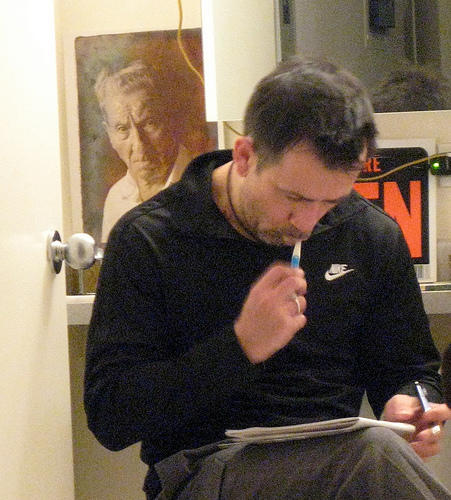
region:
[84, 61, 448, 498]
A guy sitting down writing.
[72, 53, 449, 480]
A man looking down while brushing his teeth.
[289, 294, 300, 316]
A ring.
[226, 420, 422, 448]
A white paper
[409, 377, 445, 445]
A writing utensil.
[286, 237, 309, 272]
A blue and white handled toothbrush.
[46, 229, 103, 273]
A silver doorknob.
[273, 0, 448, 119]
A mirror.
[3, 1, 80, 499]
A white door.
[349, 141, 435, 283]
A orange and black sign.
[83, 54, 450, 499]
man brushing his teeth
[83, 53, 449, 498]
man wearing black Nike brand shirt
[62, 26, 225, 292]
poster of a man on the back wall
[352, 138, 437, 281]
part of an "YES WE'RE OPEN" sign on the back wall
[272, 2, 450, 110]
mirror showing part of the back of the man's head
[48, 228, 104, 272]
silver colored doorknob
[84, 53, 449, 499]
man wearing a ring on the finger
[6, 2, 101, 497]
pink colored open door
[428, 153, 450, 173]
black box with an illuminated green light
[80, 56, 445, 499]
man looking at papers laying on his lap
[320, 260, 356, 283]
white nike logo on a black shirt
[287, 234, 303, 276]
white and blue toothbrush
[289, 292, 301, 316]
gold wedding band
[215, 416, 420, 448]
pad of paper on the man's knee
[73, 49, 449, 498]
man with brown hair brushing his teeth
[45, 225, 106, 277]
silver-colored door handle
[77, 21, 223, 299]
photo of an old man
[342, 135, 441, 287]
"open" sign with orange lettering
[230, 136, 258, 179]
man's right ear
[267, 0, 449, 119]
mirror behind the man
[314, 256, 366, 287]
white logo on black shirt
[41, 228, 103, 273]
silver metal door knob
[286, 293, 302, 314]
silver ring on finger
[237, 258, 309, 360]
hand of a person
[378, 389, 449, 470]
hand of a person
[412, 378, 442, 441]
pen used for writing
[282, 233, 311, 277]
blue and white toothbrush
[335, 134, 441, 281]
black and orange sign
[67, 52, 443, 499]
person wearing black shirt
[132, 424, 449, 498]
pair of grey pants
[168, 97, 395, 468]
this is a man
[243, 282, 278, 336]
the man is light skinned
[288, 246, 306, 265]
this is a pen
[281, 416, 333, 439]
this is a book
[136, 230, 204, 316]
this is a pullover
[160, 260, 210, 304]
the pullover is black in color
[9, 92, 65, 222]
this is the wall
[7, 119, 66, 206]
the wall is white in color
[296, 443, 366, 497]
this is a trouser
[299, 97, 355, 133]
this is the hair